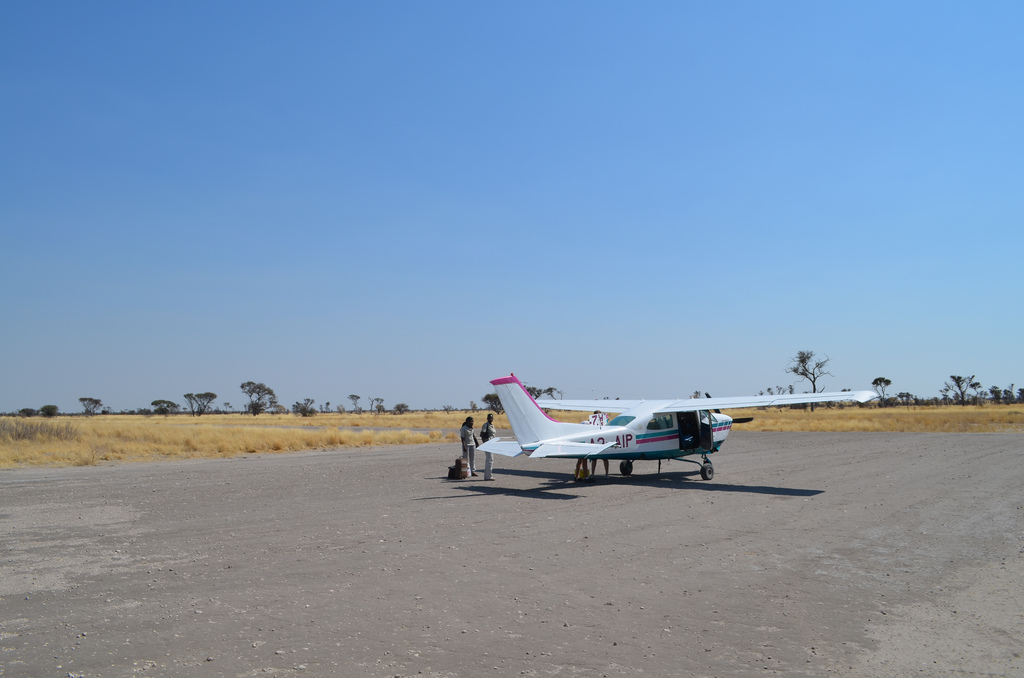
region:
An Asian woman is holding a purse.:
[454, 332, 478, 372]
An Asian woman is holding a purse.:
[410, 409, 418, 414]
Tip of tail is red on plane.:
[489, 367, 528, 393]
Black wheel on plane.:
[694, 454, 720, 489]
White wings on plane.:
[531, 375, 883, 423]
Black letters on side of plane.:
[606, 429, 632, 445]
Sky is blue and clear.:
[161, 239, 945, 350]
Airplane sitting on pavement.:
[460, 357, 878, 472]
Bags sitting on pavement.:
[441, 449, 474, 488]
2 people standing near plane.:
[441, 408, 509, 481]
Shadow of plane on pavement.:
[474, 459, 829, 514]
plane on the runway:
[473, 369, 873, 484]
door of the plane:
[678, 416, 701, 445]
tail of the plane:
[490, 375, 549, 449]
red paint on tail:
[490, 371, 554, 419]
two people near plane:
[463, 409, 495, 479]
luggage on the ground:
[444, 454, 464, 478]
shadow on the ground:
[454, 466, 824, 501]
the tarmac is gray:
[0, 425, 1018, 676]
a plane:
[471, 354, 857, 484]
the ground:
[569, 576, 659, 640]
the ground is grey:
[553, 525, 670, 666]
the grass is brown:
[130, 408, 236, 459]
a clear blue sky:
[328, 180, 525, 324]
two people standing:
[457, 408, 509, 447]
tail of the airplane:
[490, 373, 563, 434]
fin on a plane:
[497, 365, 583, 495]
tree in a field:
[72, 392, 110, 424]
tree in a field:
[37, 393, 64, 431]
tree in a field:
[151, 395, 181, 416]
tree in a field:
[186, 383, 203, 423]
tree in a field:
[197, 379, 221, 419]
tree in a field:
[242, 376, 266, 412]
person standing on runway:
[441, 403, 477, 479]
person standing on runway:
[478, 419, 508, 474]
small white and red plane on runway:
[478, 346, 875, 483]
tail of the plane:
[460, 367, 607, 470]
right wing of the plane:
[655, 378, 877, 418]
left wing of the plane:
[512, 373, 637, 427]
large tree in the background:
[787, 348, 842, 432]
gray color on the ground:
[199, 539, 547, 606]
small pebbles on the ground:
[148, 601, 373, 663]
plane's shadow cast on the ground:
[730, 459, 841, 523]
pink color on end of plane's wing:
[470, 360, 543, 395]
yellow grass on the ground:
[91, 411, 344, 488]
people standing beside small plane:
[422, 401, 514, 485]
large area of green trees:
[90, 369, 433, 421]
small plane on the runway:
[388, 341, 933, 515]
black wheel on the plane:
[684, 457, 730, 486]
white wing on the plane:
[581, 365, 921, 422]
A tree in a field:
[185, 387, 220, 420]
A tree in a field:
[157, 399, 181, 419]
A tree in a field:
[78, 394, 98, 414]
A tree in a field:
[786, 342, 825, 412]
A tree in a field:
[871, 374, 891, 400]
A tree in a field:
[939, 377, 955, 407]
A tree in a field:
[540, 387, 560, 401]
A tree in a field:
[483, 390, 507, 414]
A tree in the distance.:
[862, 370, 895, 402]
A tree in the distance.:
[898, 390, 908, 397]